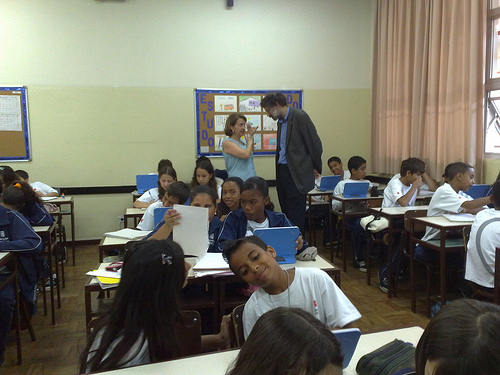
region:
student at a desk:
[232, 241, 342, 318]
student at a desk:
[113, 231, 196, 341]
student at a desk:
[226, 177, 300, 248]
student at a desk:
[160, 185, 216, 246]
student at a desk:
[380, 158, 427, 210]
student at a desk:
[156, 184, 183, 210]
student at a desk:
[395, 166, 435, 211]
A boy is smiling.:
[218, 235, 355, 330]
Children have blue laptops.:
[135, 175, 497, 367]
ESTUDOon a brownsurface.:
[196, 85, 216, 155]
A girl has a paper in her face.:
[168, 190, 209, 255]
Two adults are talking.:
[222, 92, 324, 219]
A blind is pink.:
[371, 0, 490, 190]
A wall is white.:
[2, 2, 379, 189]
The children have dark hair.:
[0, 157, 490, 366]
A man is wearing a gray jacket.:
[271, 107, 323, 192]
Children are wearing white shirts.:
[43, 162, 494, 325]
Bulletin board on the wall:
[188, 85, 304, 165]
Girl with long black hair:
[91, 237, 191, 372]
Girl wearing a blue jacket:
[218, 177, 298, 243]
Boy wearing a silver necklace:
[225, 240, 308, 305]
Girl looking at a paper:
[153, 187, 221, 260]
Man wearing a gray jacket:
[257, 93, 327, 205]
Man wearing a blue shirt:
[259, 106, 313, 173]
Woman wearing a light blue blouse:
[214, 136, 266, 181]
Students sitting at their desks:
[377, 153, 499, 222]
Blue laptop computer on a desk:
[243, 225, 310, 271]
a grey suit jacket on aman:
[270, 108, 327, 193]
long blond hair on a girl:
[78, 240, 199, 374]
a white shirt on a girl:
[423, 182, 477, 242]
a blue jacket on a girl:
[216, 206, 306, 254]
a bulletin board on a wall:
[188, 87, 310, 160]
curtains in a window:
[369, 1, 497, 191]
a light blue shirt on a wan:
[221, 136, 258, 181]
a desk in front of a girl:
[411, 202, 499, 311]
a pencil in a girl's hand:
[143, 185, 156, 198]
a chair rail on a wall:
[50, 181, 135, 197]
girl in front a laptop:
[222, 175, 310, 266]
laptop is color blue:
[247, 217, 302, 267]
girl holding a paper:
[141, 180, 222, 256]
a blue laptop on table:
[337, 175, 367, 200]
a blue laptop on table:
[130, 166, 160, 196]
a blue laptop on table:
[315, 166, 345, 191]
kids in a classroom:
[3, 82, 497, 372]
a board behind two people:
[188, 81, 309, 163]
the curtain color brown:
[364, 3, 494, 188]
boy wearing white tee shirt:
[209, 230, 364, 337]